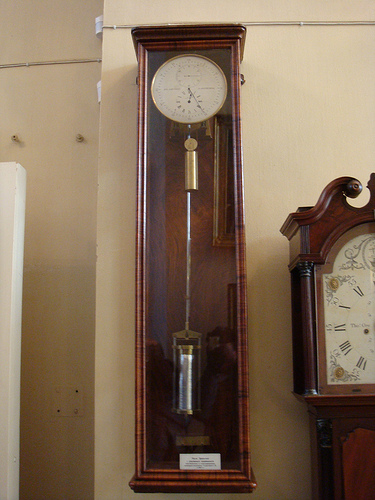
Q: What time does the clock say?
A: 6:25.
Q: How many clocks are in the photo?
A: Two.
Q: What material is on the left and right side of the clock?
A: Wood.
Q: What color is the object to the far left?
A: White.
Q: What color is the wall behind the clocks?
A: Beige.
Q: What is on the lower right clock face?
A: Flowers.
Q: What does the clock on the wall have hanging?
A: A pendulum.